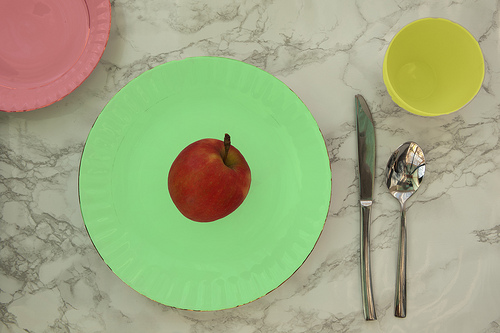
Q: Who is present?
A: Nobody.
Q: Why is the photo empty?
A: There is no one.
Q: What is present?
A: Cutlery.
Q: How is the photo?
A: Clear.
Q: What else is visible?
A: An apple.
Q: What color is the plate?
A: Green.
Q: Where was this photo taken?
A: On the table.